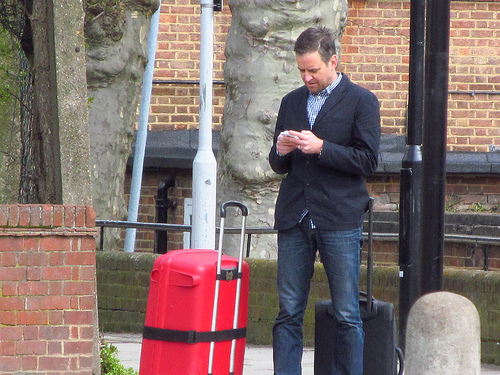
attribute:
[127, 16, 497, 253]
building — brown, brick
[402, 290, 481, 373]
cement object — circular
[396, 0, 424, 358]
metal pole — black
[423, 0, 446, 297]
metal pole — black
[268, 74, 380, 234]
jacket — blue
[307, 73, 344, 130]
shirt — striped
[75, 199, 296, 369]
suitcase — red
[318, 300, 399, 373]
suitcase — black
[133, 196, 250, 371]
suitcase — red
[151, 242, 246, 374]
suitcase — red, plastic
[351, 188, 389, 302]
handle — expandable, black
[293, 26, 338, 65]
brown hair — short